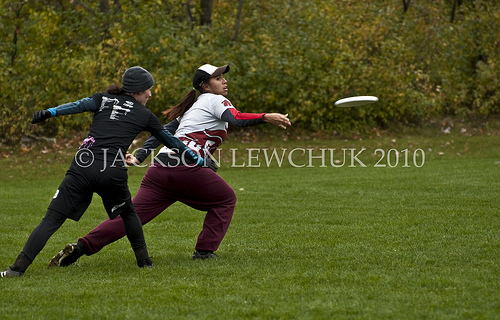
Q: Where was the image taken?
A: It was taken at the field.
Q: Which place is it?
A: It is a field.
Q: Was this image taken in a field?
A: Yes, it was taken in a field.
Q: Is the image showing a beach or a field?
A: It is showing a field.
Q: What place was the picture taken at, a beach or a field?
A: It was taken at a field.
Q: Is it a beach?
A: No, it is a field.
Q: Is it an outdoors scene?
A: Yes, it is outdoors.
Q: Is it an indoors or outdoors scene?
A: It is outdoors.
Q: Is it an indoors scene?
A: No, it is outdoors.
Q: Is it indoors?
A: No, it is outdoors.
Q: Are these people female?
A: Yes, all the people are female.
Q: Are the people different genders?
A: No, all the people are female.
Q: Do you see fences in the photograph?
A: No, there are no fences.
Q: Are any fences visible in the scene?
A: No, there are no fences.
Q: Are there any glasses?
A: No, there are no glasses.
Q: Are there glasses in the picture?
A: No, there are no glasses.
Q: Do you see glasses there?
A: No, there are no glasses.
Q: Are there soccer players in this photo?
A: No, there are no soccer players.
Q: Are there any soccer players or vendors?
A: No, there are no soccer players or vendors.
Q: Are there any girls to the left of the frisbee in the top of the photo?
A: Yes, there is a girl to the left of the frisbee.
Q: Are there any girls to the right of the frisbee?
A: No, the girl is to the left of the frisbee.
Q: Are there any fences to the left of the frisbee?
A: No, there is a girl to the left of the frisbee.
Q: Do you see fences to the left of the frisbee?
A: No, there is a girl to the left of the frisbee.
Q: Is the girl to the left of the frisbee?
A: Yes, the girl is to the left of the frisbee.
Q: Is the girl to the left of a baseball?
A: No, the girl is to the left of the frisbee.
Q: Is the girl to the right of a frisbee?
A: No, the girl is to the left of a frisbee.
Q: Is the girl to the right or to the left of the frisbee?
A: The girl is to the left of the frisbee.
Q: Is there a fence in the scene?
A: No, there are no fences.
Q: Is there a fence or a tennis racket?
A: No, there are no fences or rackets.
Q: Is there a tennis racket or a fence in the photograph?
A: No, there are no fences or rackets.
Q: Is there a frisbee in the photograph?
A: Yes, there is a frisbee.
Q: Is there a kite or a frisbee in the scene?
A: Yes, there is a frisbee.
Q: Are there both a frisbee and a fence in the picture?
A: No, there is a frisbee but no fences.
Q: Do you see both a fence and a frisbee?
A: No, there is a frisbee but no fences.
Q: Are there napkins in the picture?
A: No, there are no napkins.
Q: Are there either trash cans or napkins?
A: No, there are no napkins or trash cans.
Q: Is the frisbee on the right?
A: Yes, the frisbee is on the right of the image.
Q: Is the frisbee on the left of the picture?
A: No, the frisbee is on the right of the image.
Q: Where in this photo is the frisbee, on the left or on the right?
A: The frisbee is on the right of the image.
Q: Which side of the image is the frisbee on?
A: The frisbee is on the right of the image.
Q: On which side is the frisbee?
A: The frisbee is on the right of the image.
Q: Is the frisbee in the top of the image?
A: Yes, the frisbee is in the top of the image.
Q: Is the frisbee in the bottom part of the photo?
A: No, the frisbee is in the top of the image.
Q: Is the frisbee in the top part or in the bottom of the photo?
A: The frisbee is in the top of the image.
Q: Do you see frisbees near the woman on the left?
A: Yes, there is a frisbee near the woman.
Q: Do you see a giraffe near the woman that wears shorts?
A: No, there is a frisbee near the woman.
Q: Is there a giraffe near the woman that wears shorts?
A: No, there is a frisbee near the woman.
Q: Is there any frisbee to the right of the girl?
A: Yes, there is a frisbee to the right of the girl.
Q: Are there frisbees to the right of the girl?
A: Yes, there is a frisbee to the right of the girl.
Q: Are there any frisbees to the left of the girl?
A: No, the frisbee is to the right of the girl.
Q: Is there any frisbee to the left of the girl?
A: No, the frisbee is to the right of the girl.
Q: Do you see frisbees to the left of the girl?
A: No, the frisbee is to the right of the girl.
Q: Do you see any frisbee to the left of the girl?
A: No, the frisbee is to the right of the girl.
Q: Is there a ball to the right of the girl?
A: No, there is a frisbee to the right of the girl.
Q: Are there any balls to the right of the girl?
A: No, there is a frisbee to the right of the girl.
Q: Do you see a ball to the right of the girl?
A: No, there is a frisbee to the right of the girl.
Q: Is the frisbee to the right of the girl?
A: Yes, the frisbee is to the right of the girl.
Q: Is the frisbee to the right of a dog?
A: No, the frisbee is to the right of the girl.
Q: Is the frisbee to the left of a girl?
A: No, the frisbee is to the right of a girl.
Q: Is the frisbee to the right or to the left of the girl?
A: The frisbee is to the right of the girl.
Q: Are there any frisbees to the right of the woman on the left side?
A: Yes, there is a frisbee to the right of the woman.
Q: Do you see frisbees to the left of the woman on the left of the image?
A: No, the frisbee is to the right of the woman.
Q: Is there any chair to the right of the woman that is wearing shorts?
A: No, there is a frisbee to the right of the woman.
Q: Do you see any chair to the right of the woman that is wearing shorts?
A: No, there is a frisbee to the right of the woman.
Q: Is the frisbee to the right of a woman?
A: Yes, the frisbee is to the right of a woman.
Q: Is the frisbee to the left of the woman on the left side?
A: No, the frisbee is to the right of the woman.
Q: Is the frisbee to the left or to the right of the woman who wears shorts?
A: The frisbee is to the right of the woman.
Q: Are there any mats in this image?
A: No, there are no mats.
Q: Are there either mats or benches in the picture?
A: No, there are no mats or benches.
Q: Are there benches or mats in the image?
A: No, there are no mats or benches.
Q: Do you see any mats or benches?
A: No, there are no mats or benches.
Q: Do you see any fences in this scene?
A: No, there are no fences.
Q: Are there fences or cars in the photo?
A: No, there are no fences or cars.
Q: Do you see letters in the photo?
A: Yes, there are letters.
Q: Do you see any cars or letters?
A: Yes, there are letters.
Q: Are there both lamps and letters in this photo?
A: No, there are letters but no lamps.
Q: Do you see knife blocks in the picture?
A: No, there are no knife blocks.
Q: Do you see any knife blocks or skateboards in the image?
A: No, there are no knife blocks or skateboards.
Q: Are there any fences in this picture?
A: No, there are no fences.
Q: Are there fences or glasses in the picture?
A: No, there are no fences or glasses.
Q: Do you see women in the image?
A: Yes, there is a woman.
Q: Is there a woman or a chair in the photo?
A: Yes, there is a woman.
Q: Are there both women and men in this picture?
A: No, there is a woman but no men.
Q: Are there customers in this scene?
A: No, there are no customers.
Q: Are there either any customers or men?
A: No, there are no customers or men.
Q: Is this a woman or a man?
A: This is a woman.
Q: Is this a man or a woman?
A: This is a woman.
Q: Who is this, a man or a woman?
A: This is a woman.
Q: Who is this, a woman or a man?
A: This is a woman.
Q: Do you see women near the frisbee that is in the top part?
A: Yes, there is a woman near the frisbee.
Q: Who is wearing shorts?
A: The woman is wearing shorts.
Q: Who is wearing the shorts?
A: The woman is wearing shorts.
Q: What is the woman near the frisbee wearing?
A: The woman is wearing shorts.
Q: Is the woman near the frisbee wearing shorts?
A: Yes, the woman is wearing shorts.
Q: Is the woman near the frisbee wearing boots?
A: No, the woman is wearing shorts.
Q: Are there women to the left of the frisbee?
A: Yes, there is a woman to the left of the frisbee.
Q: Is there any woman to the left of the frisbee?
A: Yes, there is a woman to the left of the frisbee.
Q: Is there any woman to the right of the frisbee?
A: No, the woman is to the left of the frisbee.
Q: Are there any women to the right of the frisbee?
A: No, the woman is to the left of the frisbee.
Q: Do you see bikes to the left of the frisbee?
A: No, there is a woman to the left of the frisbee.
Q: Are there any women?
A: Yes, there is a woman.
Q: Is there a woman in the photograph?
A: Yes, there is a woman.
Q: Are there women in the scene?
A: Yes, there is a woman.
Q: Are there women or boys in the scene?
A: Yes, there is a woman.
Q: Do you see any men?
A: No, there are no men.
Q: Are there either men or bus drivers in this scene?
A: No, there are no men or bus drivers.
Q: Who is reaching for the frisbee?
A: The woman is reaching for the frisbee.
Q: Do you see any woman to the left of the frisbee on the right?
A: Yes, there is a woman to the left of the frisbee.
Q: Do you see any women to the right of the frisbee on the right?
A: No, the woman is to the left of the frisbee.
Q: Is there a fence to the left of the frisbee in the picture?
A: No, there is a woman to the left of the frisbee.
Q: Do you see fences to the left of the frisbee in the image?
A: No, there is a woman to the left of the frisbee.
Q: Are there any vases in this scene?
A: No, there are no vases.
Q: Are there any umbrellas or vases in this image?
A: No, there are no vases or umbrellas.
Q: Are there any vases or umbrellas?
A: No, there are no vases or umbrellas.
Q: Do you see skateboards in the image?
A: No, there are no skateboards.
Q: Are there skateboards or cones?
A: No, there are no skateboards or cones.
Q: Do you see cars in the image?
A: No, there are no cars.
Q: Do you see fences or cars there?
A: No, there are no cars or fences.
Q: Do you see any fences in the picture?
A: No, there are no fences.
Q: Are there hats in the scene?
A: Yes, there is a hat.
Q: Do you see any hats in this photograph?
A: Yes, there is a hat.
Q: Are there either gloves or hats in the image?
A: Yes, there is a hat.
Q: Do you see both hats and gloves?
A: Yes, there are both a hat and gloves.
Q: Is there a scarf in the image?
A: No, there are no scarves.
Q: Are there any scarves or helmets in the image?
A: No, there are no scarves or helmets.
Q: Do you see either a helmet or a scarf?
A: No, there are no scarves or helmets.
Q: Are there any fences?
A: No, there are no fences.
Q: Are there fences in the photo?
A: No, there are no fences.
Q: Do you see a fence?
A: No, there are no fences.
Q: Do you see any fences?
A: No, there are no fences.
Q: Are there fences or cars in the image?
A: No, there are no fences or cars.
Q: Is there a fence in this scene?
A: No, there are no fences.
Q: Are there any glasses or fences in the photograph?
A: No, there are no fences or glasses.